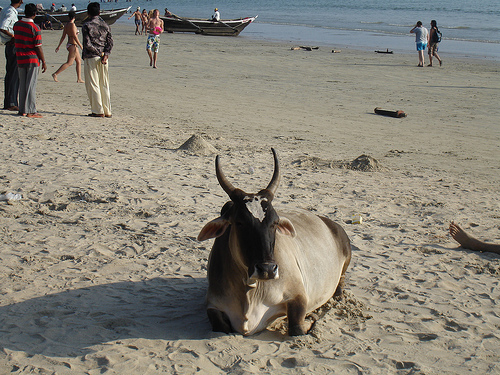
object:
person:
[427, 20, 443, 67]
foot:
[449, 221, 479, 251]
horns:
[215, 154, 235, 196]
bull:
[197, 147, 351, 337]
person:
[52, 10, 85, 84]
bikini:
[66, 28, 79, 50]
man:
[82, 2, 114, 118]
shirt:
[13, 19, 42, 68]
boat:
[159, 13, 258, 37]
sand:
[3, 56, 493, 372]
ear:
[277, 217, 298, 240]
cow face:
[229, 195, 279, 281]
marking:
[243, 195, 269, 222]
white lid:
[0, 192, 21, 200]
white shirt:
[0, 5, 19, 44]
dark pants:
[4, 37, 20, 111]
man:
[0, 0, 23, 111]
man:
[145, 9, 164, 69]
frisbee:
[151, 26, 162, 35]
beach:
[0, 23, 500, 372]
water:
[0, 0, 500, 55]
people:
[410, 21, 429, 67]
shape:
[178, 132, 220, 157]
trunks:
[146, 33, 160, 53]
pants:
[84, 56, 112, 115]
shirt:
[82, 14, 115, 61]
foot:
[51, 74, 59, 82]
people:
[212, 8, 220, 22]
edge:
[338, 46, 367, 52]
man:
[13, 3, 48, 118]